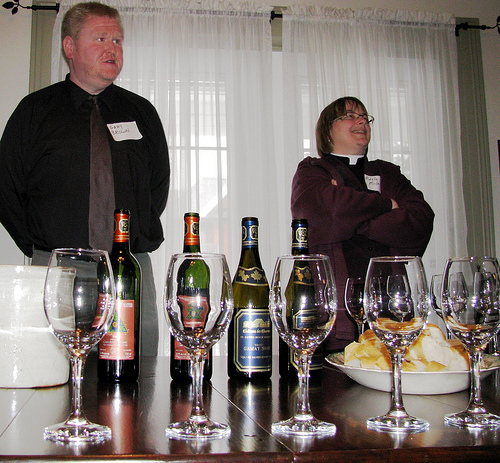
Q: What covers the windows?
A: Curtains.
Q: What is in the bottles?
A: Wine.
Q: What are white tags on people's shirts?
A: Name badges.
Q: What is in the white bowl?
A: Bread.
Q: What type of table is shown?
A: Wood.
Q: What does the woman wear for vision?
A: Glasses.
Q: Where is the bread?
A: White bowl.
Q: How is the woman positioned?
A: ARMS CROSSED.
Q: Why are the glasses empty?
A: Waiting for guests.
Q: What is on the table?
A: Wine bottles.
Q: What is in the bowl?
A: Bread.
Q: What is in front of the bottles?
A: Wine glasses.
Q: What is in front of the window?
A: Curtains.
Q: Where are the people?
A: Behind the table.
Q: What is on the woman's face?
A: Glasses.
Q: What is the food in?
A: A bowl.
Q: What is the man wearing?
A: A tie.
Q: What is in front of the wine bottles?
A: Wine glasses.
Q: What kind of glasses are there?
A: Wine.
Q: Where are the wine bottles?
A: Behind the glasses.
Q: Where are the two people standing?
A: Behind the table.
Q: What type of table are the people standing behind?
A: Dark wood.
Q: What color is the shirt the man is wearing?
A: Black.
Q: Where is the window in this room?
A: On the wall behind the people.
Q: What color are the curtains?
A: White.